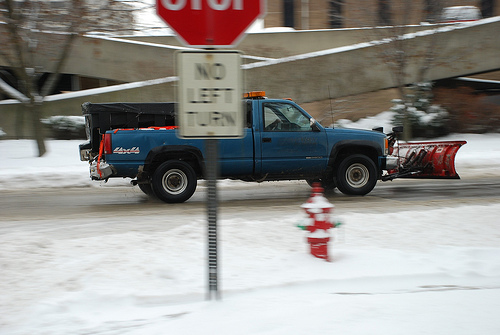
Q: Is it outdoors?
A: Yes, it is outdoors.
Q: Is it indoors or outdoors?
A: It is outdoors.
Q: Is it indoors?
A: No, it is outdoors.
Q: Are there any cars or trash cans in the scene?
A: No, there are no cars or trash cans.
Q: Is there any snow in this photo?
A: Yes, there is snow.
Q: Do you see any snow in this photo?
A: Yes, there is snow.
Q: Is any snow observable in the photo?
A: Yes, there is snow.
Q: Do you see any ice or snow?
A: Yes, there is snow.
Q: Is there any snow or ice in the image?
A: Yes, there is snow.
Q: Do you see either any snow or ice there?
A: Yes, there is snow.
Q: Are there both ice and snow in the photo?
A: No, there is snow but no ice.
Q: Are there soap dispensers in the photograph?
A: No, there are no soap dispensers.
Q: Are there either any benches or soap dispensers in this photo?
A: No, there are no soap dispensers or benches.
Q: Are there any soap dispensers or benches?
A: No, there are no soap dispensers or benches.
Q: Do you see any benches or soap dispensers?
A: No, there are no soap dispensers or benches.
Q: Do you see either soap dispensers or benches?
A: No, there are no soap dispensers or benches.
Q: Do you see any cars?
A: No, there are no cars.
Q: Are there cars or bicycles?
A: No, there are no cars or bicycles.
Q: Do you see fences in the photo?
A: No, there are no fences.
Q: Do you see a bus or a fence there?
A: No, there are no fences or buses.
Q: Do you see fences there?
A: No, there are no fences.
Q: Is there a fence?
A: No, there are no fences.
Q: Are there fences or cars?
A: No, there are no fences or cars.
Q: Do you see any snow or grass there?
A: Yes, there is snow.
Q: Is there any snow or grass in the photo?
A: Yes, there is snow.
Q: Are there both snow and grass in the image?
A: No, there is snow but no grass.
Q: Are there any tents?
A: No, there are no tents.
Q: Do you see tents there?
A: No, there are no tents.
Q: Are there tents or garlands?
A: No, there are no tents or garlands.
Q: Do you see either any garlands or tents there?
A: No, there are no tents or garlands.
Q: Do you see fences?
A: No, there are no fences.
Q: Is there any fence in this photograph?
A: No, there are no fences.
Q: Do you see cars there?
A: No, there are no cars.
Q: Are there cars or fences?
A: No, there are no cars or fences.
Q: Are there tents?
A: No, there are no tents.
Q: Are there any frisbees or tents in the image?
A: No, there are no tents or frisbees.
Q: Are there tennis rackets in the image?
A: No, there are no tennis rackets.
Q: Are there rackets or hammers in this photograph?
A: No, there are no rackets or hammers.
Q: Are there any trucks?
A: Yes, there is a truck.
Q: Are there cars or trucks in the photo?
A: Yes, there is a truck.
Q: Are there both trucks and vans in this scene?
A: No, there is a truck but no vans.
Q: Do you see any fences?
A: No, there are no fences.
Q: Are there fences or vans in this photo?
A: No, there are no fences or vans.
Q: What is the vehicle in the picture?
A: The vehicle is a truck.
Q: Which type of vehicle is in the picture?
A: The vehicle is a truck.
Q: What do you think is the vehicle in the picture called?
A: The vehicle is a truck.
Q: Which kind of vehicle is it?
A: The vehicle is a truck.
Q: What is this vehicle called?
A: This is a truck.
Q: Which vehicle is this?
A: This is a truck.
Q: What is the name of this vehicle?
A: This is a truck.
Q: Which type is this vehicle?
A: This is a truck.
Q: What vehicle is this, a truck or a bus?
A: This is a truck.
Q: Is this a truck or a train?
A: This is a truck.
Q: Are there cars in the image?
A: No, there are no cars.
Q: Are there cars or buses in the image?
A: No, there are no cars or buses.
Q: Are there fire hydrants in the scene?
A: Yes, there is a fire hydrant.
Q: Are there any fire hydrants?
A: Yes, there is a fire hydrant.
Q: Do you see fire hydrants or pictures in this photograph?
A: Yes, there is a fire hydrant.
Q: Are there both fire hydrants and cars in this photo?
A: No, there is a fire hydrant but no cars.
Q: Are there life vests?
A: No, there are no life vests.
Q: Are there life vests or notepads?
A: No, there are no life vests or notepads.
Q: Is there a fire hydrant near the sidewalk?
A: Yes, there is a fire hydrant near the sidewalk.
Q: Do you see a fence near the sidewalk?
A: No, there is a fire hydrant near the sidewalk.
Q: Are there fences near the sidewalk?
A: No, there is a fire hydrant near the sidewalk.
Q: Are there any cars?
A: No, there are no cars.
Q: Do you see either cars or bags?
A: No, there are no cars or bags.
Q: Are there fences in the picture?
A: No, there are no fences.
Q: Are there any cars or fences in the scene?
A: No, there are no fences or cars.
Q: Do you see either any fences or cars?
A: No, there are no fences or cars.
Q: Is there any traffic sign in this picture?
A: Yes, there is a traffic sign.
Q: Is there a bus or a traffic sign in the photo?
A: Yes, there is a traffic sign.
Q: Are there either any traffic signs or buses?
A: Yes, there is a traffic sign.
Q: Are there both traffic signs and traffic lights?
A: No, there is a traffic sign but no traffic lights.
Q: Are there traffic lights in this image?
A: No, there are no traffic lights.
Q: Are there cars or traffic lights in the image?
A: No, there are no traffic lights or cars.